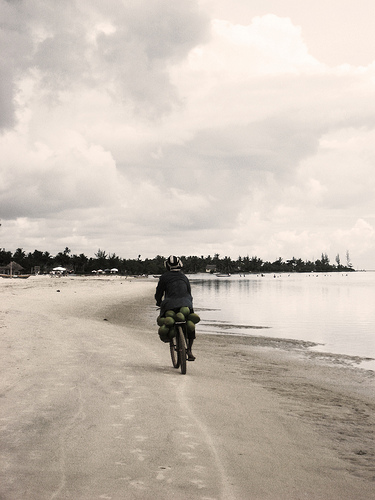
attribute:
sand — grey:
[5, 309, 117, 426]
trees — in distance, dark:
[1, 236, 316, 278]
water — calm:
[213, 278, 369, 369]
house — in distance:
[45, 268, 82, 282]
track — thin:
[154, 383, 232, 499]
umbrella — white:
[93, 262, 118, 272]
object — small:
[48, 289, 70, 295]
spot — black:
[52, 275, 69, 299]